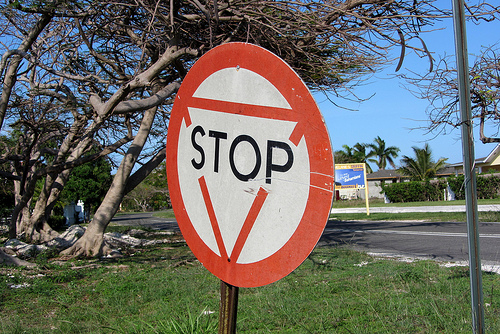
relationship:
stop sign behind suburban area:
[156, 34, 341, 295] [6, 118, 498, 225]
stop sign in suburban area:
[163, 40, 335, 289] [6, 105, 497, 220]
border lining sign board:
[162, 38, 335, 288] [163, 40, 336, 287]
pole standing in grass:
[451, 0, 484, 330] [1, 219, 480, 332]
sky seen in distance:
[1, 1, 482, 172] [1, 0, 481, 218]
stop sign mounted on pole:
[163, 40, 335, 289] [216, 280, 238, 331]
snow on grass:
[5, 248, 497, 313] [1, 219, 480, 332]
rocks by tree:
[15, 231, 81, 269] [1, 128, 162, 280]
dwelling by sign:
[380, 145, 497, 204] [315, 148, 387, 218]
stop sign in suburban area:
[156, 34, 341, 295] [6, 105, 497, 220]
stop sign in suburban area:
[156, 34, 341, 295] [1, 122, 499, 212]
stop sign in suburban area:
[156, 34, 341, 295] [1, 113, 499, 207]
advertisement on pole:
[335, 162, 369, 192] [352, 184, 361, 200]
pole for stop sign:
[212, 279, 243, 332] [163, 40, 335, 289]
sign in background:
[338, 163, 368, 191] [336, 129, 484, 233]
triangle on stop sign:
[176, 94, 306, 264] [163, 40, 335, 289]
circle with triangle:
[162, 40, 338, 290] [176, 94, 306, 264]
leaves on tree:
[411, 147, 431, 168] [399, 140, 451, 180]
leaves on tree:
[366, 150, 379, 159] [361, 132, 399, 172]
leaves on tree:
[361, 140, 377, 151] [360, 135, 398, 171]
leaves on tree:
[70, 173, 90, 194] [8, 117, 115, 226]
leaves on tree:
[422, 152, 430, 174] [398, 140, 448, 185]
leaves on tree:
[1, 172, 11, 191] [0, 131, 20, 214]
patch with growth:
[403, 283, 449, 323] [422, 297, 453, 319]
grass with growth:
[308, 287, 376, 332] [330, 296, 354, 319]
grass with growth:
[0, 219, 499, 333] [306, 290, 326, 312]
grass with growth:
[0, 219, 499, 333] [379, 296, 415, 318]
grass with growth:
[0, 219, 499, 333] [77, 289, 112, 321]